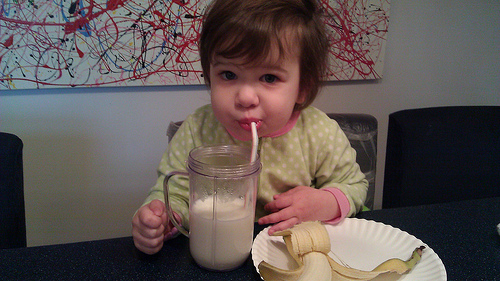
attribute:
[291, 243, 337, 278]
banana — peeled, ripe, eaten, still, white, yellow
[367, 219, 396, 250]
plate — white, sitting, full, close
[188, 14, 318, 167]
girl — drinking, looking, young, watching, sucking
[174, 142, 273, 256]
glass — clear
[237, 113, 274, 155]
straw — white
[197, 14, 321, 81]
hair — short, light brown